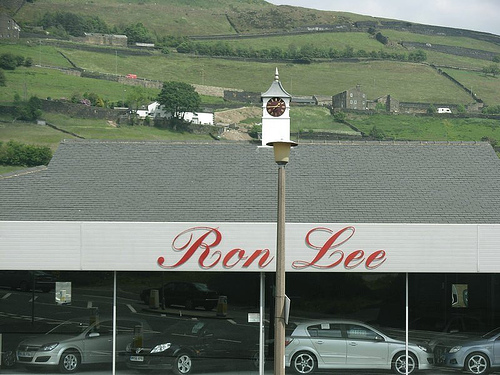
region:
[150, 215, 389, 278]
large RON LEE letters on wall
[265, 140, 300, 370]
a tan and white light pole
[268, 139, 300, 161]
a tan and white light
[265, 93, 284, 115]
a black and gold silver clock face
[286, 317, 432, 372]
a silver car parked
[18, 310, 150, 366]
a silver car parked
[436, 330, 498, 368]
a silver car parked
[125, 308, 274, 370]
a black car parked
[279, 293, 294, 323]
a white sign hanging on a pole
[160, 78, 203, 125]
a large leafy tree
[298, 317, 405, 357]
this is a car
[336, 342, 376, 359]
the car is white in color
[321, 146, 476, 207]
this is the roof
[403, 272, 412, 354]
this is a pole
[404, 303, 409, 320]
the pole is white in color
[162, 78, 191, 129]
this is a tree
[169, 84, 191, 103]
the tree has green leaves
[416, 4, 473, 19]
this is the sky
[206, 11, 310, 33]
this is a hill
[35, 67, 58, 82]
this is a grass area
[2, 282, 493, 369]
cars in the window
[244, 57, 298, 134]
a brown clock with gold numbers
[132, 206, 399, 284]
the letters are red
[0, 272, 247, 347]
reflection of the street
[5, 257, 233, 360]
reflection of parked cars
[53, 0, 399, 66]
a huge hill in the background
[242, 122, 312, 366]
a tall beige pole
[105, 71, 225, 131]
a big white house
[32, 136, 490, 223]
the roof of the building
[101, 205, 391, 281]
the letters spell ron lee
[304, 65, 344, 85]
this is the grass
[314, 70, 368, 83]
the grass is green in color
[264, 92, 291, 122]
this is the clock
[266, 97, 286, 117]
the clock is small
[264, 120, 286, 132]
the wall is white in color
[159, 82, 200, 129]
this is a tree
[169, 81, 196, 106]
the leaves are green in color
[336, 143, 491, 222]
this is a roof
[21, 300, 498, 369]
these are some cars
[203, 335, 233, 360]
the car is black in color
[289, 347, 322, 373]
the wheel on a car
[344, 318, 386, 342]
the window on a car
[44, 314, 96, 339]
a windshield on a car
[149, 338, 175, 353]
a headlight on a car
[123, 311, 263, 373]
a black car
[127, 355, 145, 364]
a white license plate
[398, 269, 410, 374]
a gray metal pole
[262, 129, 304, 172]
a lamp on a post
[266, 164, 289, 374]
a metal lamp post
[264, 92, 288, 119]
a clock on a tower